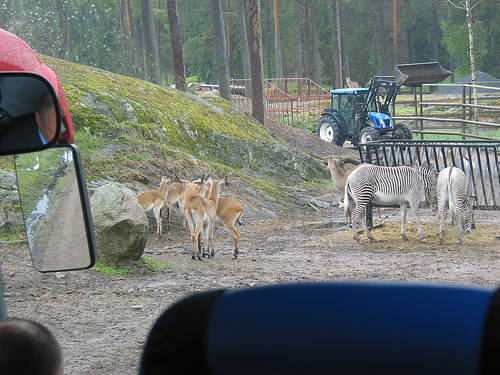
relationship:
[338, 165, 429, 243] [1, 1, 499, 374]
zebra in scene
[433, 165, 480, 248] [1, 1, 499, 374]
zebra in scene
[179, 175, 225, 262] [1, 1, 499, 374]
antelope in scene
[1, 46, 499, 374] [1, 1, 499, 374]
ground in scene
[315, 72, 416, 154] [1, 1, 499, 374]
tractor in scene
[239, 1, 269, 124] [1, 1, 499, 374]
tree in scene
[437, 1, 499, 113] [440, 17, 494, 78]
tree has leaves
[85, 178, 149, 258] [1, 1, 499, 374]
rock in scene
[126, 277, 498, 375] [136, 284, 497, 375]
chair has a back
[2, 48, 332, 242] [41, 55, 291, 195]
rock covered in moss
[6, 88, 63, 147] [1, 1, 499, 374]
man in scene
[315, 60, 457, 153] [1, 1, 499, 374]
tractor in scene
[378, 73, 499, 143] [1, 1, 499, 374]
fence in scene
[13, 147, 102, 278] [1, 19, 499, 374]
mirror on vehicle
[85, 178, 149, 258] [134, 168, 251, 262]
rock next to antelopes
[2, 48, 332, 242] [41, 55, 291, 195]
hill covered in moss